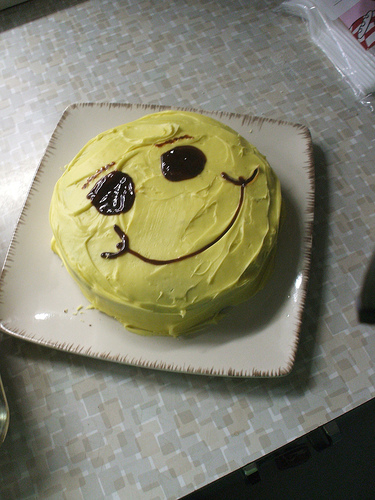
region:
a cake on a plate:
[11, 11, 344, 491]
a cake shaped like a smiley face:
[53, 108, 306, 335]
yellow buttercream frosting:
[124, 270, 200, 315]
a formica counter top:
[54, 383, 220, 485]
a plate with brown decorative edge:
[210, 352, 344, 402]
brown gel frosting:
[171, 151, 197, 171]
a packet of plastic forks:
[292, 9, 364, 68]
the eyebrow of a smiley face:
[150, 129, 195, 145]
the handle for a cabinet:
[283, 409, 353, 472]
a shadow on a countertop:
[9, 5, 77, 33]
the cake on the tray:
[75, 99, 281, 332]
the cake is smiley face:
[78, 127, 262, 315]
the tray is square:
[0, 79, 317, 394]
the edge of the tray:
[294, 196, 313, 293]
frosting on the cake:
[77, 120, 282, 305]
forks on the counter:
[285, 0, 371, 99]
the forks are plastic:
[265, 0, 370, 112]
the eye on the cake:
[92, 171, 124, 205]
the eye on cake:
[157, 142, 211, 191]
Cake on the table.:
[51, 101, 285, 342]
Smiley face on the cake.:
[40, 100, 290, 341]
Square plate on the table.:
[0, 88, 343, 396]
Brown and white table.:
[0, 0, 372, 498]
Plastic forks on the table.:
[278, 2, 373, 103]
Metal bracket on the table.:
[220, 419, 356, 497]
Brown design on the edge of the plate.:
[2, 93, 318, 384]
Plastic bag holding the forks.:
[271, 0, 373, 107]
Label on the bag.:
[317, 1, 374, 51]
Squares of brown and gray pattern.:
[5, 5, 373, 499]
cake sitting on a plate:
[24, 106, 313, 343]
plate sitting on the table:
[40, 92, 370, 470]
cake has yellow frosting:
[68, 131, 238, 312]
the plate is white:
[9, 245, 112, 398]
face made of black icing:
[79, 149, 154, 240]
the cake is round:
[50, 98, 276, 332]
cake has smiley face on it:
[57, 131, 260, 315]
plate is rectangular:
[24, 62, 295, 442]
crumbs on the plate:
[50, 286, 102, 352]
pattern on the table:
[24, 30, 161, 108]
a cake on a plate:
[69, 47, 372, 355]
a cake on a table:
[34, 107, 367, 455]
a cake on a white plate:
[65, 118, 374, 404]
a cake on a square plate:
[64, 62, 346, 415]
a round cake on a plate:
[56, 74, 365, 458]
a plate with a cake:
[43, 98, 365, 365]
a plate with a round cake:
[89, 45, 300, 379]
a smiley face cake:
[64, 110, 371, 455]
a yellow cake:
[84, 95, 356, 399]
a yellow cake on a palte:
[59, 117, 374, 408]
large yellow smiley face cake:
[51, 107, 281, 336]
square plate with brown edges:
[0, 101, 316, 377]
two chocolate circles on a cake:
[84, 142, 206, 214]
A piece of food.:
[53, 77, 285, 323]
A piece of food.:
[155, 142, 215, 185]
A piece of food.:
[90, 167, 146, 229]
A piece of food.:
[149, 120, 201, 159]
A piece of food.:
[29, 91, 292, 374]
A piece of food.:
[44, 121, 209, 356]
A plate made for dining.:
[4, 95, 325, 388]